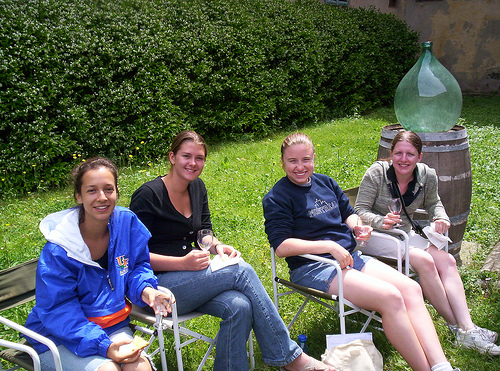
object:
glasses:
[355, 208, 373, 238]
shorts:
[286, 247, 368, 295]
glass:
[187, 226, 218, 249]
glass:
[148, 285, 175, 317]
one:
[131, 128, 498, 371]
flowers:
[228, 135, 268, 180]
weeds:
[217, 201, 257, 244]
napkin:
[414, 224, 459, 253]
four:
[22, 129, 497, 371]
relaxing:
[48, 219, 407, 371]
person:
[16, 156, 176, 371]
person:
[356, 129, 499, 355]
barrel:
[425, 126, 474, 222]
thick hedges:
[113, 86, 196, 136]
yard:
[40, 104, 397, 267]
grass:
[7, 214, 34, 260]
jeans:
[158, 259, 303, 371]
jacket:
[20, 198, 161, 359]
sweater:
[260, 177, 359, 271]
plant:
[0, 11, 116, 53]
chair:
[269, 230, 401, 336]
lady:
[261, 130, 449, 370]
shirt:
[354, 158, 448, 229]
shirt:
[128, 172, 216, 274]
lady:
[129, 127, 343, 370]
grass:
[329, 122, 377, 150]